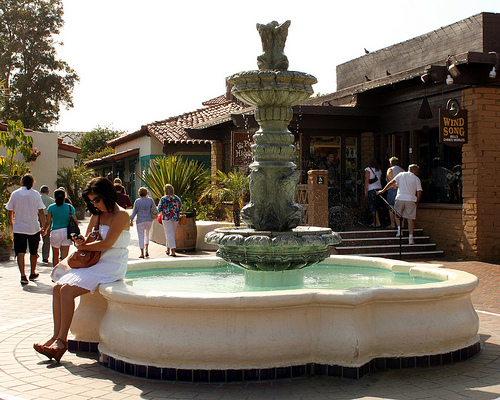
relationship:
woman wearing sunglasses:
[33, 175, 131, 365] [89, 195, 99, 203]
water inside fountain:
[131, 260, 442, 289] [68, 20, 484, 379]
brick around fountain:
[66, 340, 481, 382] [68, 20, 484, 379]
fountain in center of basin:
[68, 20, 484, 379] [68, 256, 480, 375]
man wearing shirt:
[3, 174, 47, 287] [4, 186, 48, 234]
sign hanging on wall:
[437, 99, 469, 144] [377, 90, 478, 259]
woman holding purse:
[33, 175, 131, 365] [69, 215, 105, 268]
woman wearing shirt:
[40, 189, 84, 265] [46, 201, 77, 232]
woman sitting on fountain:
[33, 175, 131, 365] [68, 20, 484, 379]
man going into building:
[376, 163, 424, 245] [185, 26, 500, 259]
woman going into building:
[361, 157, 389, 228] [185, 26, 500, 259]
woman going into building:
[384, 156, 404, 229] [185, 26, 500, 259]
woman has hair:
[33, 175, 131, 365] [83, 176, 118, 214]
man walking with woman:
[3, 174, 47, 287] [40, 189, 84, 265]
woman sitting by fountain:
[33, 175, 131, 365] [68, 20, 484, 379]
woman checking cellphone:
[33, 175, 131, 365] [69, 232, 77, 240]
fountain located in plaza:
[68, 20, 484, 379] [0, 208, 497, 398]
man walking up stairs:
[376, 163, 424, 245] [330, 226, 443, 261]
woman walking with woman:
[125, 186, 161, 259] [157, 184, 186, 257]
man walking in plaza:
[3, 174, 47, 287] [0, 208, 497, 398]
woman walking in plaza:
[40, 189, 84, 265] [0, 208, 497, 398]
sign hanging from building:
[437, 99, 469, 144] [185, 26, 500, 259]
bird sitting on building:
[362, 75, 371, 82] [185, 26, 500, 259]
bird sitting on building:
[364, 47, 370, 57] [185, 26, 500, 259]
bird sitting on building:
[384, 69, 392, 78] [185, 26, 500, 259]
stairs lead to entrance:
[330, 226, 443, 261] [306, 132, 362, 225]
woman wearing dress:
[33, 175, 131, 365] [52, 229, 131, 293]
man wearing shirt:
[376, 163, 424, 245] [393, 171, 422, 202]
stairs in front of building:
[330, 226, 443, 261] [185, 26, 500, 259]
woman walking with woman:
[157, 184, 186, 257] [125, 186, 161, 259]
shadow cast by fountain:
[38, 336, 499, 396] [68, 20, 484, 379]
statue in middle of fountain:
[253, 20, 292, 70] [68, 20, 484, 379]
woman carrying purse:
[40, 189, 84, 265] [68, 202, 82, 242]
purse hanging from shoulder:
[68, 202, 82, 242] [65, 202, 76, 214]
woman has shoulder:
[40, 189, 84, 265] [65, 202, 76, 214]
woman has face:
[33, 175, 131, 365] [86, 192, 106, 215]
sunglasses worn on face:
[89, 195, 99, 203] [86, 192, 106, 215]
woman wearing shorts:
[40, 189, 84, 265] [50, 229, 70, 248]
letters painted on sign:
[442, 115, 465, 136] [437, 99, 469, 144]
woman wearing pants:
[157, 184, 186, 257] [163, 219, 180, 250]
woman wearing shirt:
[157, 184, 186, 257] [156, 195, 182, 219]